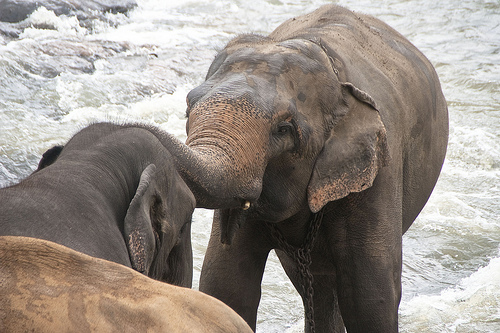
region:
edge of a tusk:
[239, 198, 256, 219]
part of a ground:
[433, 220, 460, 258]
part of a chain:
[293, 264, 319, 306]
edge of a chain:
[269, 223, 284, 245]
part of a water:
[431, 271, 454, 318]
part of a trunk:
[215, 184, 237, 207]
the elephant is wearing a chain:
[226, 141, 345, 306]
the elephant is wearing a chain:
[270, 190, 325, 324]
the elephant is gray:
[54, 147, 151, 240]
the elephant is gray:
[33, 100, 188, 290]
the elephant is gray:
[104, 107, 233, 282]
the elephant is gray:
[245, 181, 384, 297]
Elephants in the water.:
[146, 5, 414, 329]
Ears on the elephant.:
[285, 64, 390, 217]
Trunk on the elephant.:
[113, 87, 318, 230]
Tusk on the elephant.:
[209, 168, 278, 285]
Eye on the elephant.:
[271, 99, 343, 162]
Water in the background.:
[54, 9, 281, 196]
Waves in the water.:
[26, 17, 191, 193]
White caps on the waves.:
[63, 29, 275, 216]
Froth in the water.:
[54, 17, 133, 126]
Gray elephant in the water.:
[136, 24, 453, 331]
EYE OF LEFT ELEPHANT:
[271, 114, 310, 150]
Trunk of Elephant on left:
[128, 114, 233, 194]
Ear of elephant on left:
[306, 79, 388, 216]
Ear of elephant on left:
[124, 163, 169, 273]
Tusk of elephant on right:
[242, 197, 257, 212]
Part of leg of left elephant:
[205, 215, 268, 293]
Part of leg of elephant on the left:
[335, 227, 385, 260]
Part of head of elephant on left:
[217, 29, 339, 113]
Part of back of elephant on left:
[362, 47, 424, 89]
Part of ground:
[112, 40, 179, 93]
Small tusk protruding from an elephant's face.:
[242, 196, 254, 213]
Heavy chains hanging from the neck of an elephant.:
[268, 214, 324, 330]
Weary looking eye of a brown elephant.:
[280, 119, 292, 137]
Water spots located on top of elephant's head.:
[241, 45, 337, 131]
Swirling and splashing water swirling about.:
[30, 9, 250, 28]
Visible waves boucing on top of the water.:
[414, 253, 499, 300]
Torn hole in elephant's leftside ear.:
[330, 78, 390, 195]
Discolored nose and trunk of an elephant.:
[192, 93, 266, 178]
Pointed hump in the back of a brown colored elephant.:
[319, 4, 349, 50]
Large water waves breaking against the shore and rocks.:
[4, 6, 180, 116]